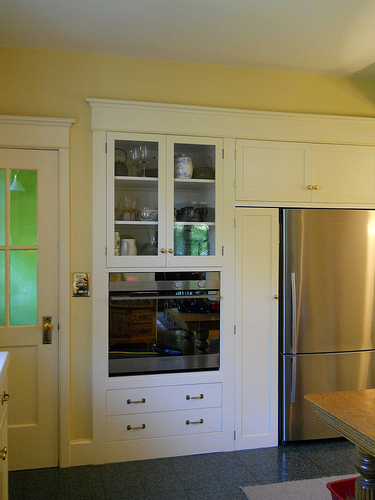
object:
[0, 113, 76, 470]
white frame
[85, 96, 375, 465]
cabinets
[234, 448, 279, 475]
tile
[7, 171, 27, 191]
light fixture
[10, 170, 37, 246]
window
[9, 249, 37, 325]
window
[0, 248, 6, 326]
window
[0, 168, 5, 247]
window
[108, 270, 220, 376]
oven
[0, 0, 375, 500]
kitchen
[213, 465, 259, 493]
tile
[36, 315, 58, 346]
knob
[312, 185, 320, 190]
knob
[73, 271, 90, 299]
light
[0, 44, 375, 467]
wall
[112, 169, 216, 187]
shelf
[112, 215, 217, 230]
shelf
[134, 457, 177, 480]
tile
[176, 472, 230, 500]
tile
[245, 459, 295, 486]
tile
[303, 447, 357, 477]
tile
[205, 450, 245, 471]
tile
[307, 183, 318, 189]
handle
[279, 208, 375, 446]
fridge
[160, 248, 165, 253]
golden knob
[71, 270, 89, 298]
light switch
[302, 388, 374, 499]
kitchen counter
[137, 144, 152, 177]
wine glass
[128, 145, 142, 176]
wine glass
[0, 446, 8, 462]
handle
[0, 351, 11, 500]
cabinet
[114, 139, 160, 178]
cabinet window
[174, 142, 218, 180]
cabinet window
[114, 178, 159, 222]
cabinet window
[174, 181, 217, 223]
cabinet window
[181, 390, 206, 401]
handle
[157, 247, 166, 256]
handle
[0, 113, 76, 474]
door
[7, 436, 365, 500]
gray tile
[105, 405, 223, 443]
drawer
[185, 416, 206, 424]
handle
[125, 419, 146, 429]
handle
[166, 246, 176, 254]
knob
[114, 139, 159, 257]
window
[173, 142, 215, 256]
window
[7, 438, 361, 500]
floor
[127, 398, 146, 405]
handle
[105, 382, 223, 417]
drawer